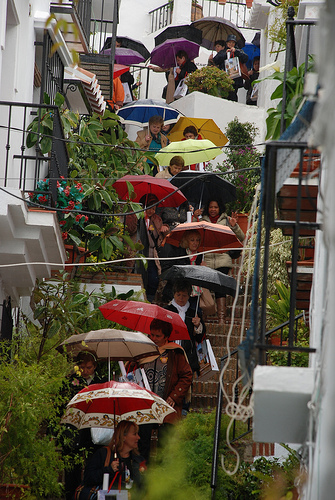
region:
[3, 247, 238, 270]
white cable running above walkway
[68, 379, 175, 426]
red and white umbrella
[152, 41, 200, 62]
man holding purple umbrella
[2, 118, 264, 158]
black cable running above walkway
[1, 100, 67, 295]
balcony with black railing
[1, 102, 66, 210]
black railing of balcony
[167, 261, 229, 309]
woman holding black umbrella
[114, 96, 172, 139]
woman holding blue and white umbrella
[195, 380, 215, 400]
red brick steps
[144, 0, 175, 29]
black safety railing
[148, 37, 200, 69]
A purple umbrella a man is holding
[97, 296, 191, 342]
A red umbrella held by a short brown haired woman in a brown coat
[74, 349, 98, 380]
Head of a brown haired woman wearing a light green headband.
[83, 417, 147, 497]
A light brown haired woman carrying a brown strap purse on her shoulder.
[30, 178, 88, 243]
A large bunch of bright green leaved flowers with red blossoms.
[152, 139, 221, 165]
A very light colored yellow umbrella.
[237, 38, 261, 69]
A solid blue umbrella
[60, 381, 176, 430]
A red umbrella with a thick white and gold band around the bottom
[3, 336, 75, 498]
Bright green leaves on a tree to the left of the bottom most woman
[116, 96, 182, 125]
A blue umbrella with white trim by a man in orange.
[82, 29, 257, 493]
Line of women on stairs with umbrellas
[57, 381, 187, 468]
Blond woman with umbrella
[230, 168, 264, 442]
Metal hand rails for stairs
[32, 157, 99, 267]
Flowers hanging of steps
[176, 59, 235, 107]
Plant at corner of steps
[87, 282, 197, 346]
Red umbrellas held by woman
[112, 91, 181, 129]
Blue umbrellas held by woman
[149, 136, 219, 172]
Yellow umbrellas held by woman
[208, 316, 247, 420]
Red brick stairs between buildings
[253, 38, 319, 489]
White building with balcony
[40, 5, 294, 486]
people holding umbrellas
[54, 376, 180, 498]
woman holds a white and red umbrella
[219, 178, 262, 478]
a rope is hunging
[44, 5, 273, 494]
people going down the stairs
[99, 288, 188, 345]
woman holding a red umbrella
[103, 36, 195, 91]
two people with purple umbrellas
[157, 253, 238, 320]
woman holding a black umbrella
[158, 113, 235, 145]
woman holding a yellow umbrella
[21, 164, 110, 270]
red flowers on side stairs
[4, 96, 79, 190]
black rail on side stairs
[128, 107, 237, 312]
People with umbrellas.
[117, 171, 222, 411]
People walking down the stairs.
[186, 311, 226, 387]
A lady carrying shopping bag.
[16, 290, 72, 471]
Trees next to the stores.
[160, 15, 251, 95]
People on top of the stairs.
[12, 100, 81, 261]
Balcony on the building.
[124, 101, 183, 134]
The lady is carrying a white and blue umbrella.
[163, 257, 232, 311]
The lady is carrying a black umbrella.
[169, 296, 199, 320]
The woman is wearing a white scarf around neck.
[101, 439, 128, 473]
The lady hand is on the umbrella handle.